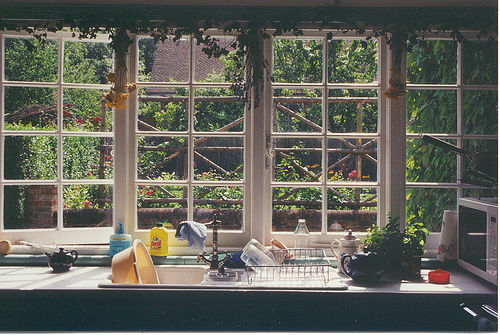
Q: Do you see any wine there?
A: No, there is no wine.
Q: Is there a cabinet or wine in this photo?
A: No, there are no wine or cabinets.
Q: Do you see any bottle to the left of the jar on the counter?
A: Yes, there are bottles to the left of the jar.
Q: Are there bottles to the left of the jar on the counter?
A: Yes, there are bottles to the left of the jar.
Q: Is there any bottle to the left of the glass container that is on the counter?
A: Yes, there are bottles to the left of the jar.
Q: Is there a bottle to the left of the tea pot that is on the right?
A: Yes, there are bottles to the left of the tea pot.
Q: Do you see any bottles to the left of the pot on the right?
A: Yes, there are bottles to the left of the pot.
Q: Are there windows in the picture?
A: Yes, there is a window.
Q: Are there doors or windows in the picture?
A: Yes, there is a window.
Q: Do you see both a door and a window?
A: No, there is a window but no doors.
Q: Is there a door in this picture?
A: No, there are no doors.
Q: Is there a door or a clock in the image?
A: No, there are no doors or clocks.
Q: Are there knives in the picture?
A: No, there are no knives.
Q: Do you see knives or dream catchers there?
A: No, there are no knives or dream catchers.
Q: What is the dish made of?
A: The dish is made of plastic.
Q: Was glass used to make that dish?
A: No, the dish is made of plastic.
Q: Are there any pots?
A: Yes, there is a pot.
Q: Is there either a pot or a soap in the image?
A: Yes, there is a pot.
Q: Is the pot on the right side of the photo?
A: Yes, the pot is on the right of the image.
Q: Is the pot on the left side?
A: No, the pot is on the right of the image.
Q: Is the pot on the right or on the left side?
A: The pot is on the right of the image.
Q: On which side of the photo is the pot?
A: The pot is on the right of the image.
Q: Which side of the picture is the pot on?
A: The pot is on the right of the image.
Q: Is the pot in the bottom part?
A: Yes, the pot is in the bottom of the image.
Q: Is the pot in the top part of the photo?
A: No, the pot is in the bottom of the image.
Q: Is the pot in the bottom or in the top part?
A: The pot is in the bottom of the image.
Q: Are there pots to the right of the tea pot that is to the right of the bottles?
A: Yes, there is a pot to the right of the tea pot.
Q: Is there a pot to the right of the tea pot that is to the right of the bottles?
A: Yes, there is a pot to the right of the tea pot.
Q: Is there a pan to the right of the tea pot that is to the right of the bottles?
A: No, there is a pot to the right of the tea pot.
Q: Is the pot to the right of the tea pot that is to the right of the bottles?
A: Yes, the pot is to the right of the tea pot.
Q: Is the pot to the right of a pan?
A: No, the pot is to the right of the tea pot.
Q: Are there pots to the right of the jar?
A: Yes, there is a pot to the right of the jar.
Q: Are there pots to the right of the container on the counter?
A: Yes, there is a pot to the right of the jar.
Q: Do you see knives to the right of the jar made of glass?
A: No, there is a pot to the right of the jar.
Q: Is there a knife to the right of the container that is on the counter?
A: No, there is a pot to the right of the jar.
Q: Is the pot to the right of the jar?
A: Yes, the pot is to the right of the jar.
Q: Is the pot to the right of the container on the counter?
A: Yes, the pot is to the right of the jar.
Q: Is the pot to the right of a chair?
A: No, the pot is to the right of the jar.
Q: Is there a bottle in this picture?
A: Yes, there is a bottle.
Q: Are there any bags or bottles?
A: Yes, there is a bottle.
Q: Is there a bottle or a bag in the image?
A: Yes, there is a bottle.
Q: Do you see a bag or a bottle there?
A: Yes, there is a bottle.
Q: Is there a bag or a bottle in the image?
A: Yes, there is a bottle.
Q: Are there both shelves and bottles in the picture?
A: No, there is a bottle but no shelves.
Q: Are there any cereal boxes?
A: No, there are no cereal boxes.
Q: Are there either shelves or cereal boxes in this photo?
A: No, there are no cereal boxes or shelves.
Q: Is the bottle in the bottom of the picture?
A: Yes, the bottle is in the bottom of the image.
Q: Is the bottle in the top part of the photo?
A: No, the bottle is in the bottom of the image.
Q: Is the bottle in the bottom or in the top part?
A: The bottle is in the bottom of the image.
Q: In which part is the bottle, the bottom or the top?
A: The bottle is in the bottom of the image.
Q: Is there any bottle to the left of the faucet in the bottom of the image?
A: Yes, there is a bottle to the left of the tap.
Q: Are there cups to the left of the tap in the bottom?
A: No, there is a bottle to the left of the faucet.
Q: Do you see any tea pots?
A: Yes, there is a tea pot.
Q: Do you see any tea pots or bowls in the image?
A: Yes, there is a tea pot.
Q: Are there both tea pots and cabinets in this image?
A: No, there is a tea pot but no cabinets.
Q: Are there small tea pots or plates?
A: Yes, there is a small tea pot.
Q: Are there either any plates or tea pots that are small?
A: Yes, the tea pot is small.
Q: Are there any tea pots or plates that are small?
A: Yes, the tea pot is small.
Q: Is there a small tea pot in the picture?
A: Yes, there is a small tea pot.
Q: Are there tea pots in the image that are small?
A: Yes, there is a tea pot that is small.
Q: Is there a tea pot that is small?
A: Yes, there is a tea pot that is small.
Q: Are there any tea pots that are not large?
A: Yes, there is a small tea pot.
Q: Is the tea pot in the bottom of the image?
A: Yes, the tea pot is in the bottom of the image.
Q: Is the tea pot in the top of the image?
A: No, the tea pot is in the bottom of the image.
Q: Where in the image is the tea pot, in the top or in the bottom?
A: The tea pot is in the bottom of the image.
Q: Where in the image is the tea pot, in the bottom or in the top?
A: The tea pot is in the bottom of the image.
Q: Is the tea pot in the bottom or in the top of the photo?
A: The tea pot is in the bottom of the image.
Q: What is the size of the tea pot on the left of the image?
A: The tea pot is small.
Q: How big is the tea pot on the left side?
A: The tea pot is small.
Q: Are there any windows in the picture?
A: Yes, there is a window.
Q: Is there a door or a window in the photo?
A: Yes, there is a window.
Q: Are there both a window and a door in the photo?
A: No, there is a window but no doors.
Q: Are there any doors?
A: No, there are no doors.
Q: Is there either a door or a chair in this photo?
A: No, there are no doors or chairs.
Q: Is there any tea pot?
A: Yes, there is a tea pot.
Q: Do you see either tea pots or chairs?
A: Yes, there is a tea pot.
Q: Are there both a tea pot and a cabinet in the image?
A: No, there is a tea pot but no cabinets.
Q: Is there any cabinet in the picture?
A: No, there are no cabinets.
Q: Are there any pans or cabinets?
A: No, there are no cabinets or pans.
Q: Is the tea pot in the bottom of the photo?
A: Yes, the tea pot is in the bottom of the image.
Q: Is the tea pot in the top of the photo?
A: No, the tea pot is in the bottom of the image.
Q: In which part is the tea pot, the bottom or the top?
A: The tea pot is in the bottom of the image.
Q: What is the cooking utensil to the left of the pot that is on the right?
A: The cooking utensil is a tea pot.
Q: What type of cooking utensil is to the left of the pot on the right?
A: The cooking utensil is a tea pot.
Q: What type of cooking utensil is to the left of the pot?
A: The cooking utensil is a tea pot.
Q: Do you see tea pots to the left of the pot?
A: Yes, there is a tea pot to the left of the pot.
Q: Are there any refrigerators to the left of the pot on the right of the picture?
A: No, there is a tea pot to the left of the pot.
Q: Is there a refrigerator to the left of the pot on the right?
A: No, there is a tea pot to the left of the pot.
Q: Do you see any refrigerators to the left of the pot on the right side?
A: No, there is a tea pot to the left of the pot.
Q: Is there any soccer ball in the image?
A: No, there are no soccer balls.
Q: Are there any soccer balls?
A: No, there are no soccer balls.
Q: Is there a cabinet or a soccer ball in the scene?
A: No, there are no soccer balls or cabinets.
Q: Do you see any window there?
A: Yes, there is a window.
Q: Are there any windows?
A: Yes, there is a window.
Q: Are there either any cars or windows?
A: Yes, there is a window.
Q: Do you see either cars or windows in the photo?
A: Yes, there is a window.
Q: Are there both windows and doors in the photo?
A: No, there is a window but no doors.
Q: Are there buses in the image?
A: No, there are no buses.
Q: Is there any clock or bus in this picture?
A: No, there are no buses or clocks.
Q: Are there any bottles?
A: Yes, there is a bottle.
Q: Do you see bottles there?
A: Yes, there is a bottle.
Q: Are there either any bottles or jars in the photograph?
A: Yes, there is a bottle.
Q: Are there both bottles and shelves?
A: No, there is a bottle but no shelves.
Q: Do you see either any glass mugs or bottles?
A: Yes, there is a glass bottle.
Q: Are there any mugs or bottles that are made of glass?
A: Yes, the bottle is made of glass.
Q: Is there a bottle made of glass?
A: Yes, there is a bottle that is made of glass.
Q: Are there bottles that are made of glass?
A: Yes, there is a bottle that is made of glass.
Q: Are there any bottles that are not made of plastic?
A: Yes, there is a bottle that is made of glass.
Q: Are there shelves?
A: No, there are no shelves.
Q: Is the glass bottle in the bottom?
A: Yes, the bottle is in the bottom of the image.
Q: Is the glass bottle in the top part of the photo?
A: No, the bottle is in the bottom of the image.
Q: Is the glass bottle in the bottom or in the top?
A: The bottle is in the bottom of the image.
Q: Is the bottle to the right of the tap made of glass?
A: Yes, the bottle is made of glass.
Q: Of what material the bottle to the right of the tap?
A: The bottle is made of glass.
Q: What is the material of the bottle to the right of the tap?
A: The bottle is made of glass.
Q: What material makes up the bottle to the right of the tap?
A: The bottle is made of glass.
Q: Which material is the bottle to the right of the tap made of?
A: The bottle is made of glass.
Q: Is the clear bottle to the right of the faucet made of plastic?
A: No, the bottle is made of glass.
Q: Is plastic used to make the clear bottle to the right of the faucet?
A: No, the bottle is made of glass.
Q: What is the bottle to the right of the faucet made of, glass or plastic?
A: The bottle is made of glass.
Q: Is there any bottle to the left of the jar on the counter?
A: Yes, there is a bottle to the left of the jar.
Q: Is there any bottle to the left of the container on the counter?
A: Yes, there is a bottle to the left of the jar.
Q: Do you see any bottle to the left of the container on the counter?
A: Yes, there is a bottle to the left of the jar.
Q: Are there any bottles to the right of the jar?
A: No, the bottle is to the left of the jar.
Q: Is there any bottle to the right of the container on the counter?
A: No, the bottle is to the left of the jar.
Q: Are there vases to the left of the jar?
A: No, there is a bottle to the left of the jar.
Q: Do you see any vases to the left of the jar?
A: No, there is a bottle to the left of the jar.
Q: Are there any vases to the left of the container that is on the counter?
A: No, there is a bottle to the left of the jar.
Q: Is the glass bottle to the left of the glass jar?
A: Yes, the bottle is to the left of the jar.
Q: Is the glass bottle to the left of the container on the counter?
A: Yes, the bottle is to the left of the jar.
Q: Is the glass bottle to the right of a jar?
A: No, the bottle is to the left of a jar.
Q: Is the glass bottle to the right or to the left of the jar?
A: The bottle is to the left of the jar.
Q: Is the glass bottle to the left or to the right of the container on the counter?
A: The bottle is to the left of the jar.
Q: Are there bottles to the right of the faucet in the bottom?
A: Yes, there is a bottle to the right of the faucet.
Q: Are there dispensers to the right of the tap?
A: No, there is a bottle to the right of the tap.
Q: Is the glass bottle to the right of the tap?
A: Yes, the bottle is to the right of the tap.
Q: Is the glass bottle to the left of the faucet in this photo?
A: No, the bottle is to the right of the faucet.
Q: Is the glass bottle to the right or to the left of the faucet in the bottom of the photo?
A: The bottle is to the right of the tap.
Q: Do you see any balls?
A: No, there are no balls.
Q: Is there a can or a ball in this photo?
A: No, there are no balls or cans.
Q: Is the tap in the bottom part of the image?
A: Yes, the tap is in the bottom of the image.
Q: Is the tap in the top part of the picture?
A: No, the tap is in the bottom of the image.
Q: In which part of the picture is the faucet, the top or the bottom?
A: The faucet is in the bottom of the image.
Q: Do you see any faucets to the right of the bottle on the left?
A: Yes, there is a faucet to the right of the bottle.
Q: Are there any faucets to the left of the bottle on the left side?
A: No, the faucet is to the right of the bottle.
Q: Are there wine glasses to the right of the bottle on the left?
A: No, there is a faucet to the right of the bottle.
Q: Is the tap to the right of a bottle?
A: Yes, the tap is to the right of a bottle.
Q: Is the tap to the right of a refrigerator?
A: No, the tap is to the right of a bottle.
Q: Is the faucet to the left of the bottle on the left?
A: No, the faucet is to the right of the bottle.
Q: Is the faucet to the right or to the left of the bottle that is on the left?
A: The faucet is to the right of the bottle.